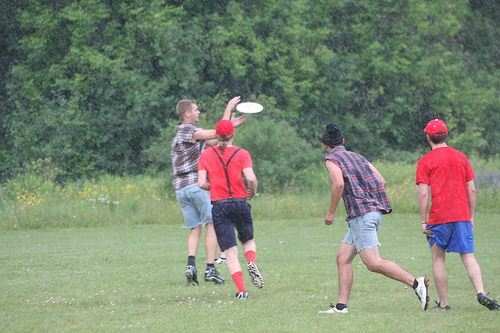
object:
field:
[0, 0, 499, 332]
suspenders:
[209, 146, 243, 203]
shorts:
[425, 221, 473, 254]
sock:
[230, 270, 245, 294]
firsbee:
[235, 101, 265, 114]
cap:
[215, 119, 234, 136]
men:
[415, 118, 499, 311]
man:
[170, 95, 264, 286]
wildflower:
[77, 169, 150, 205]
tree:
[0, 0, 173, 180]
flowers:
[0, 176, 53, 229]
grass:
[0, 215, 499, 332]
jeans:
[341, 211, 383, 253]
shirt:
[322, 145, 393, 221]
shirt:
[197, 145, 252, 200]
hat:
[422, 119, 448, 136]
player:
[197, 119, 265, 299]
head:
[319, 124, 345, 153]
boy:
[314, 123, 430, 314]